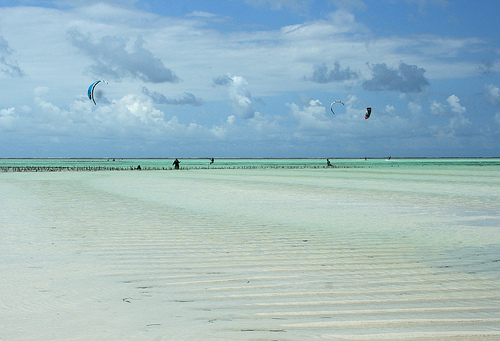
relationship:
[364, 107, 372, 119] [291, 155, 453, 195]
kite over beach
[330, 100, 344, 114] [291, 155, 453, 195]
kite over beach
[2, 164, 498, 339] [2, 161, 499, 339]
sand on an island beach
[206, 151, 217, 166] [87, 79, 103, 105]
person with kite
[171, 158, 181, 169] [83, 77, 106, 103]
people watching kite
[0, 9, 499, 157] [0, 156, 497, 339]
clouds over ocean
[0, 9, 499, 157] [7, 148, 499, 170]
clouds over ocean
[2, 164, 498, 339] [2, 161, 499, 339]
sand on beach